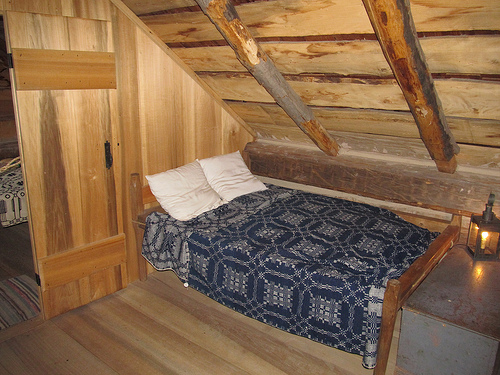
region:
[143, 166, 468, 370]
a bed in a room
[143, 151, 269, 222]
two white pillows on the bed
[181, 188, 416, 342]
a blue bed spread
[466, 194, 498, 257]
a light on the dresser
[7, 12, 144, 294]
a large wooden door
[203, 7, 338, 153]
a log hanging from the ceiling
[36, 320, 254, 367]
the hardwood floor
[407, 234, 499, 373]
a brown dresser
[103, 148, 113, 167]
the knob on the door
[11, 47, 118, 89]
a piece of wood on the door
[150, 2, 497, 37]
wooden board in gabled wall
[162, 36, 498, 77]
wooden board in gabled wall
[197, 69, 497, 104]
wooden board in gabled wall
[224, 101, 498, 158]
wooden board in gabled wall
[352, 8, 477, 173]
vertical wooden supports in wall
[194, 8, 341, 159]
vertical wooden supports in wall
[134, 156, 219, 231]
white pillow on bed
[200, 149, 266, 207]
white pillow on bed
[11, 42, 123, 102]
horizontal wood support on door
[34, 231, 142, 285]
horizontal wood support on door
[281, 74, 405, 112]
brown wooden roof board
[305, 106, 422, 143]
brown wooden roof board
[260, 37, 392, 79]
brown wooden roof board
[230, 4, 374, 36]
brown wooden roof board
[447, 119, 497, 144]
brown wooden roof board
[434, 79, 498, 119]
brown wooden roof board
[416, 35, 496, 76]
brown wooden roof board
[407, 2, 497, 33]
brown wooden roof board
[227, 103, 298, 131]
brown wooden roof board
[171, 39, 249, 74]
brown wooden roof board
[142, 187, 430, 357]
the blue and white bedspread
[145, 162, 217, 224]
the square white pillow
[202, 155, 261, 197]
the square white pillow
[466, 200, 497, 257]
the metal lamp by the bed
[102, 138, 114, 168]
the black door handle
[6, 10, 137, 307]
the light wooden door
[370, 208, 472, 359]
the wooden footboard of the bed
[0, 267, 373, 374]
the wooden floor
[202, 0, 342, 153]
the exposed log on the wall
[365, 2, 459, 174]
the exposed log on the wall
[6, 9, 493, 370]
a bedroom under a roof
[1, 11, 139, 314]
the door of bedroom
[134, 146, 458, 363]
bed is covered with a blue comforter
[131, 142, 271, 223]
two pillows on a bed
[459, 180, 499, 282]
a light is on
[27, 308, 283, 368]
floor of room si wood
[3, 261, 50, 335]
a rug behind a door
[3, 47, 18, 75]
a black hinge on door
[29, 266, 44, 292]
a black hinge on door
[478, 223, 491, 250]
an electric bulb in a lamp